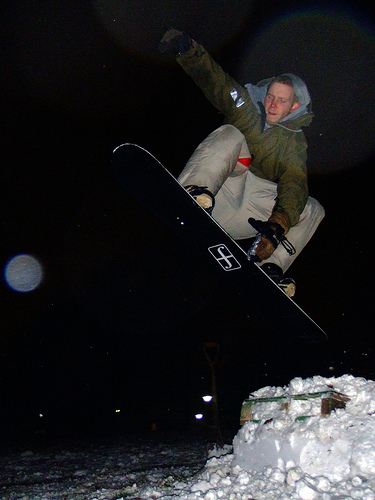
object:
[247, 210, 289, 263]
hand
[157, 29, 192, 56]
hand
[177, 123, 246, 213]
leg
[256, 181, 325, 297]
leg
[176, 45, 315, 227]
jacket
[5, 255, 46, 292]
moon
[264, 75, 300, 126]
head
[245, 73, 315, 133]
hood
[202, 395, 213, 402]
lights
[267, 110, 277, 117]
mouth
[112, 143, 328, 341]
snow board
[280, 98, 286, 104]
eye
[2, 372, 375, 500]
snow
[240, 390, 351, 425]
ramp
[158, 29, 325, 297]
guy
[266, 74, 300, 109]
hair